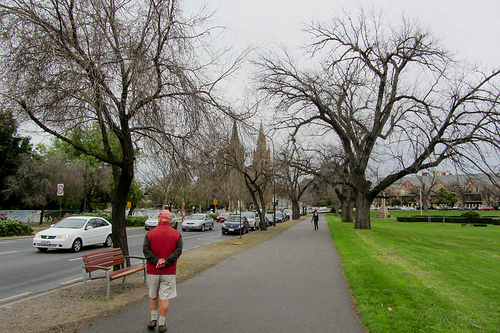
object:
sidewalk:
[235, 199, 346, 328]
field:
[327, 208, 477, 331]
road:
[11, 208, 213, 259]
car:
[144, 179, 234, 261]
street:
[1, 214, 239, 306]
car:
[32, 208, 117, 253]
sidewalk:
[50, 210, 372, 330]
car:
[222, 215, 248, 232]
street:
[0, 238, 93, 297]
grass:
[413, 245, 470, 291]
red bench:
[81, 248, 146, 290]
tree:
[332, 22, 399, 239]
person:
[140, 198, 179, 330]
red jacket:
[142, 224, 183, 276]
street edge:
[183, 231, 265, 252]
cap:
[158, 208, 174, 220]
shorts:
[145, 273, 176, 299]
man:
[127, 201, 187, 331]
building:
[191, 109, 361, 249]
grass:
[210, 227, 246, 261]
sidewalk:
[300, 200, 332, 247]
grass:
[370, 225, 498, 331]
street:
[165, 167, 360, 332]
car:
[213, 195, 315, 240]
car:
[182, 210, 216, 232]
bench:
[78, 239, 153, 308]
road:
[15, 161, 218, 285]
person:
[306, 204, 323, 231]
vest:
[142, 232, 182, 272]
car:
[151, 212, 237, 239]